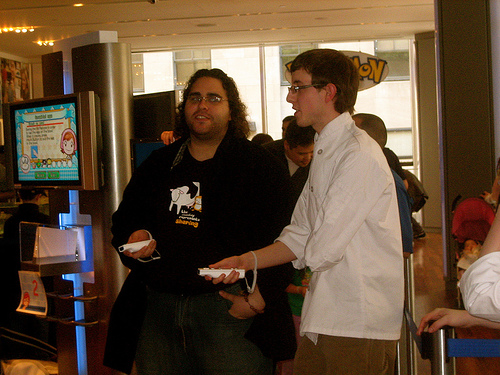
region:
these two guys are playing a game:
[92, 55, 424, 362]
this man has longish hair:
[163, 53, 255, 180]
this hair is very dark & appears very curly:
[162, 49, 260, 161]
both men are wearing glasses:
[181, 76, 402, 120]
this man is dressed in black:
[131, 133, 296, 370]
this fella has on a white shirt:
[272, 116, 420, 368]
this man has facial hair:
[166, 60, 256, 162]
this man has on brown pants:
[288, 294, 415, 374]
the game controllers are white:
[116, 231, 308, 329]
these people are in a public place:
[33, 6, 466, 367]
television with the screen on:
[9, 90, 103, 192]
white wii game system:
[32, 225, 77, 267]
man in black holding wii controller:
[106, 67, 296, 374]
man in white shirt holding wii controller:
[196, 47, 403, 373]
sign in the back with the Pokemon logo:
[284, 50, 389, 93]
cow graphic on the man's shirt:
[166, 177, 201, 213]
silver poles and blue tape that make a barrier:
[400, 252, 498, 372]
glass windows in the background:
[132, 37, 419, 228]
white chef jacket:
[276, 111, 405, 344]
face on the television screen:
[57, 125, 76, 158]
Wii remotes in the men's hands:
[72, 227, 279, 296]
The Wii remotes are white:
[86, 217, 266, 295]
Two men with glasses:
[140, 55, 393, 139]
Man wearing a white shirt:
[258, 20, 404, 368]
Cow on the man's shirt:
[148, 167, 213, 229]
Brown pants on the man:
[290, 320, 410, 370]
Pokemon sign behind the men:
[267, 45, 408, 100]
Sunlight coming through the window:
[105, 39, 442, 222]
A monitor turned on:
[0, 92, 105, 199]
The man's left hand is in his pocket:
[193, 280, 290, 327]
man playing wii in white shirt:
[251, 50, 404, 352]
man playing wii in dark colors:
[121, 56, 253, 338]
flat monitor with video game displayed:
[9, 92, 102, 195]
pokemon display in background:
[294, 53, 385, 98]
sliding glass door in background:
[132, 28, 419, 282]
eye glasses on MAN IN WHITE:
[278, 81, 330, 94]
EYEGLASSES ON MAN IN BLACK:
[176, 82, 231, 104]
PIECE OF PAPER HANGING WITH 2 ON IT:
[10, 258, 72, 315]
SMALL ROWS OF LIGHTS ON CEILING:
[17, 16, 49, 58]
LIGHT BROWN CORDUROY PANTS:
[288, 321, 405, 363]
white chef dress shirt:
[289, 151, 421, 334]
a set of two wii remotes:
[131, 230, 291, 292]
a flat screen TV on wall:
[22, 96, 137, 212]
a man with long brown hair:
[169, 77, 246, 133]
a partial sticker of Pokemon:
[308, 28, 418, 94]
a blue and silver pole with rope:
[405, 294, 481, 372]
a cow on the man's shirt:
[172, 170, 235, 247]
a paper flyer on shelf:
[2, 257, 79, 321]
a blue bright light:
[49, 88, 102, 353]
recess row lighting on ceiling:
[12, 17, 58, 58]